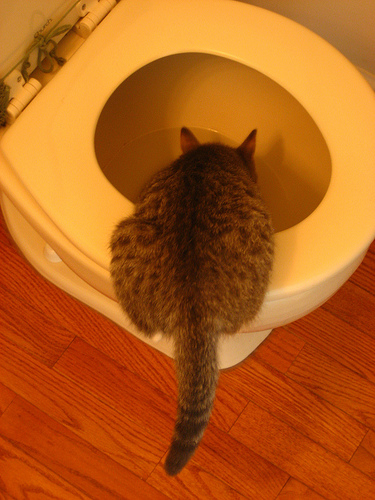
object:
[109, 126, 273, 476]
cat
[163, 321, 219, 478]
tail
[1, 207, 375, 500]
floor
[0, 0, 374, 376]
toilet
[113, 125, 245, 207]
water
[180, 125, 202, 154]
ear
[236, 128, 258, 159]
ear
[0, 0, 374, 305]
seat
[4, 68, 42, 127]
hinge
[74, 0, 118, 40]
hinge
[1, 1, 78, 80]
toilet seat cover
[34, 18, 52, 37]
word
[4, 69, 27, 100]
screw cap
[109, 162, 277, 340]
back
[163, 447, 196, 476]
tip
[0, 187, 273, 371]
base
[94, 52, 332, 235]
bowl